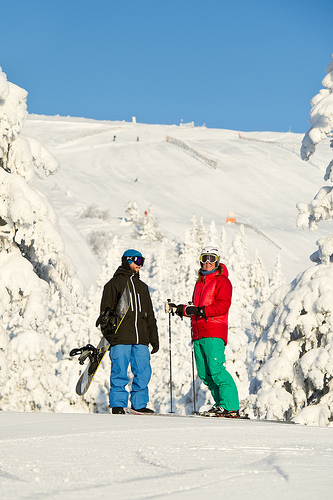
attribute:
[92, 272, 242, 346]
jacket — black, lack, red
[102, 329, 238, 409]
pants — green, blue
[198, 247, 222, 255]
helmet — white